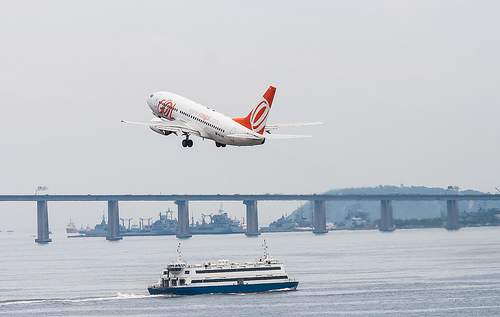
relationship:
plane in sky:
[133, 79, 323, 150] [6, 8, 500, 241]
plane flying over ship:
[133, 79, 323, 150] [149, 242, 301, 298]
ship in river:
[149, 242, 301, 298] [9, 214, 500, 308]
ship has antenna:
[149, 242, 301, 298] [252, 235, 274, 265]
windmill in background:
[133, 214, 151, 239] [6, 8, 490, 231]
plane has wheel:
[133, 79, 323, 150] [180, 136, 196, 153]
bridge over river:
[10, 179, 500, 238] [9, 214, 500, 308]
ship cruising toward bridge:
[60, 214, 85, 239] [10, 179, 500, 238]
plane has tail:
[133, 79, 323, 150] [233, 84, 279, 142]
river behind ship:
[9, 214, 500, 308] [149, 242, 301, 298]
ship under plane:
[149, 242, 301, 298] [133, 79, 323, 150]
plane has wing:
[133, 79, 323, 150] [120, 103, 201, 142]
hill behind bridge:
[262, 184, 494, 227] [10, 179, 500, 238]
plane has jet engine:
[133, 79, 323, 150] [144, 117, 176, 142]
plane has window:
[133, 79, 323, 150] [174, 106, 186, 117]